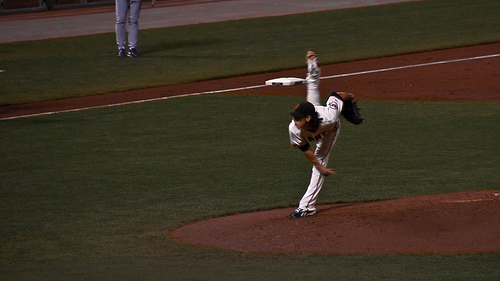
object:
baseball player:
[287, 47, 365, 218]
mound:
[167, 189, 500, 255]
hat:
[288, 100, 317, 115]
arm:
[287, 130, 335, 176]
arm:
[326, 90, 358, 116]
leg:
[287, 135, 342, 219]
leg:
[303, 48, 321, 109]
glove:
[340, 99, 365, 125]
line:
[0, 52, 500, 121]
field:
[0, 0, 497, 280]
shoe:
[287, 209, 319, 219]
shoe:
[305, 49, 320, 76]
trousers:
[297, 129, 340, 210]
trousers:
[302, 75, 320, 106]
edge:
[0, 0, 403, 43]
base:
[263, 76, 306, 87]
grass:
[1, 99, 497, 200]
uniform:
[286, 68, 347, 210]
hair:
[310, 109, 322, 130]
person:
[112, 1, 144, 59]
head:
[288, 102, 317, 129]